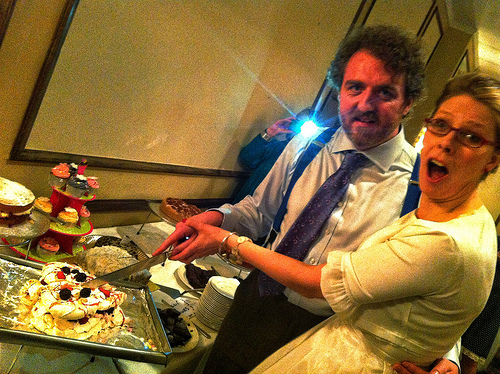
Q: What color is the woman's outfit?
A: White.